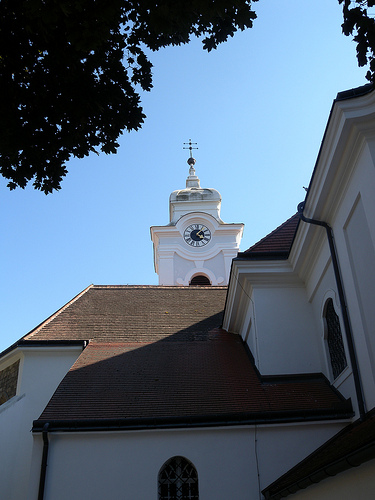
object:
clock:
[184, 224, 211, 248]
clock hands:
[197, 232, 205, 241]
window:
[320, 296, 355, 389]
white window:
[155, 453, 199, 498]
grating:
[173, 43, 211, 464]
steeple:
[150, 139, 245, 287]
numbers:
[203, 232, 212, 237]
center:
[192, 228, 204, 242]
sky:
[0, 1, 375, 348]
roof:
[35, 338, 359, 425]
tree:
[0, 0, 259, 194]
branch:
[338, 1, 374, 81]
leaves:
[354, 33, 369, 53]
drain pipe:
[296, 198, 366, 415]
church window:
[190, 273, 210, 288]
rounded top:
[319, 292, 341, 326]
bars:
[175, 460, 185, 498]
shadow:
[28, 308, 337, 429]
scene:
[0, 0, 374, 499]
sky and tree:
[0, 0, 375, 354]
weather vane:
[181, 136, 199, 167]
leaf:
[203, 35, 222, 51]